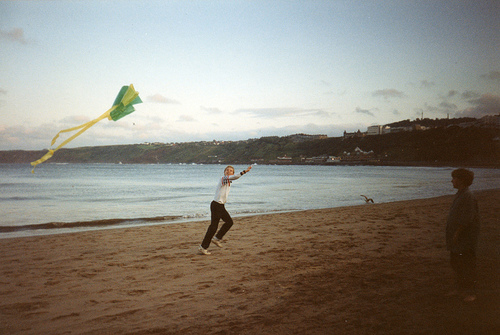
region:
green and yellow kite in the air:
[14, 55, 157, 174]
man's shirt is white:
[203, 175, 249, 211]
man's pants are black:
[202, 196, 243, 248]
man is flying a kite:
[174, 155, 272, 257]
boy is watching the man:
[428, 150, 493, 310]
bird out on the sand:
[357, 189, 381, 216]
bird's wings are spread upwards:
[360, 187, 386, 217]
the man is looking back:
[182, 157, 266, 257]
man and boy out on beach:
[2, 0, 498, 333]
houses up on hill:
[333, 107, 498, 140]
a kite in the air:
[28, 84, 160, 172]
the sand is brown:
[262, 242, 359, 301]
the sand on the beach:
[52, 250, 139, 307]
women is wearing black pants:
[207, 205, 236, 235]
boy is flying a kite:
[190, 156, 267, 253]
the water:
[75, 163, 162, 199]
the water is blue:
[72, 173, 160, 202]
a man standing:
[445, 168, 485, 306]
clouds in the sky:
[365, 82, 413, 102]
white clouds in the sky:
[149, 89, 280, 117]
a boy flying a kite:
[42, 64, 275, 293]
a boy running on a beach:
[192, 139, 274, 274]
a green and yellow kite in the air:
[42, 78, 159, 185]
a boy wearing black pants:
[196, 201, 248, 249]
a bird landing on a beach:
[340, 179, 388, 229]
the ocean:
[20, 153, 210, 238]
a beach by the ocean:
[23, 134, 343, 334]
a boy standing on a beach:
[437, 150, 482, 310]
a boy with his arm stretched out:
[220, 149, 273, 189]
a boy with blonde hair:
[218, 159, 238, 183]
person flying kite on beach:
[213, 155, 245, 234]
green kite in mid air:
[110, 87, 148, 122]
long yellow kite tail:
[41, 107, 118, 167]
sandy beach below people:
[50, 187, 453, 331]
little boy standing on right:
[438, 148, 481, 303]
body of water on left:
[2, 151, 399, 231]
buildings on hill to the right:
[324, 93, 467, 144]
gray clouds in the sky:
[363, 80, 408, 102]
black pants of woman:
[215, 195, 242, 244]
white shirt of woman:
[205, 171, 240, 198]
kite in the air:
[27, 81, 144, 175]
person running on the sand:
[200, 164, 257, 255]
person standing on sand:
[443, 169, 478, 304]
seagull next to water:
[360, 191, 376, 203]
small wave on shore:
[0, 214, 191, 233]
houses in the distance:
[341, 113, 499, 140]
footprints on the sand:
[1, 201, 499, 334]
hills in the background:
[0, 114, 499, 168]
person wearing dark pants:
[197, 165, 261, 255]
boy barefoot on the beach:
[446, 164, 478, 303]